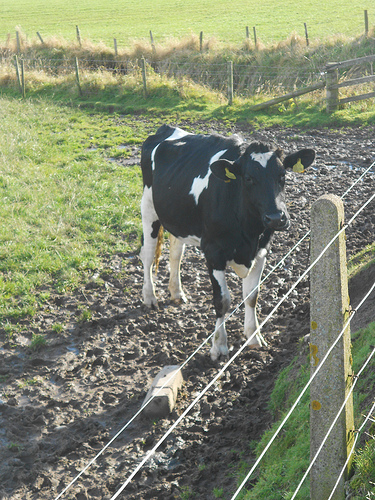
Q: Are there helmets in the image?
A: No, there are no helmets.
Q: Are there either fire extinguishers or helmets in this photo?
A: No, there are no helmets or fire extinguishers.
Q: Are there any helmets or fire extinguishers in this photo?
A: No, there are no helmets or fire extinguishers.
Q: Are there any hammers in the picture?
A: No, there are no hammers.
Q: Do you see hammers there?
A: No, there are no hammers.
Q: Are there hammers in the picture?
A: No, there are no hammers.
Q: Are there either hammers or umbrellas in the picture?
A: No, there are no hammers or umbrellas.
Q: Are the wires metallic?
A: Yes, the wires are metallic.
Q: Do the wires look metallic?
A: Yes, the wires are metallic.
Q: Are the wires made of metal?
A: Yes, the wires are made of metal.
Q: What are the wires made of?
A: The wires are made of metal.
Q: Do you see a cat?
A: No, there are no cats.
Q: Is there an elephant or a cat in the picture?
A: No, there are no cats or elephants.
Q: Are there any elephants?
A: No, there are no elephants.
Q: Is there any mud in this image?
A: Yes, there is mud.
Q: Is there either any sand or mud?
A: Yes, there is mud.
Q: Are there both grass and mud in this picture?
A: Yes, there are both mud and grass.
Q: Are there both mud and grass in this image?
A: Yes, there are both mud and grass.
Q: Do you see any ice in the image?
A: No, there is no ice.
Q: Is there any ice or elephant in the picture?
A: No, there are no ice or elephants.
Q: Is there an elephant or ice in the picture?
A: No, there are no ice or elephants.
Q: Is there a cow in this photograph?
A: Yes, there is a cow.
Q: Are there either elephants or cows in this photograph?
A: Yes, there is a cow.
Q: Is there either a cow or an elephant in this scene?
A: Yes, there is a cow.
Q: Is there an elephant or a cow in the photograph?
A: Yes, there is a cow.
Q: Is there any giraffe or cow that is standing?
A: Yes, the cow is standing.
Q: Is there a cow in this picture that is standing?
A: Yes, there is a cow that is standing.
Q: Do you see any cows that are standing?
A: Yes, there is a cow that is standing.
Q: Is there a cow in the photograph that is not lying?
A: Yes, there is a cow that is standing.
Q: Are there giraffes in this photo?
A: No, there are no giraffes.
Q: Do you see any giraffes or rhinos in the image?
A: No, there are no giraffes or rhinos.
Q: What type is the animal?
A: The animal is a cow.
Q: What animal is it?
A: The animal is a cow.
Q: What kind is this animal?
A: This is a cow.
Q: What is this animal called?
A: This is a cow.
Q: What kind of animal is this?
A: This is a cow.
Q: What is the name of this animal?
A: This is a cow.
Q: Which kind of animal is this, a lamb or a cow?
A: This is a cow.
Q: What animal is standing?
A: The animal is a cow.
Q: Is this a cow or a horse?
A: This is a cow.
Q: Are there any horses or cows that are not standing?
A: No, there is a cow but it is standing.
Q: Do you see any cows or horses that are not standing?
A: No, there is a cow but it is standing.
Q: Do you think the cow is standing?
A: Yes, the cow is standing.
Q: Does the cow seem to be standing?
A: Yes, the cow is standing.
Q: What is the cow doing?
A: The cow is standing.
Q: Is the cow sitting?
A: No, the cow is standing.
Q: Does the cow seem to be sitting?
A: No, the cow is standing.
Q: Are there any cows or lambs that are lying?
A: No, there is a cow but it is standing.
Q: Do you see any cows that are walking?
A: No, there is a cow but it is standing.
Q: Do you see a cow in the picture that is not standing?
A: No, there is a cow but it is standing.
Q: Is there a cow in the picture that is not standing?
A: No, there is a cow but it is standing.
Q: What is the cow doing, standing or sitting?
A: The cow is standing.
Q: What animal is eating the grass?
A: The cow is eating the grass.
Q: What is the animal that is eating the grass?
A: The animal is a cow.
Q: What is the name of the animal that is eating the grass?
A: The animal is a cow.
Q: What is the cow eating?
A: The cow is eating grass.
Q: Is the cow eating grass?
A: Yes, the cow is eating grass.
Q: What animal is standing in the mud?
A: The cow is standing in the mud.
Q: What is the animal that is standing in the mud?
A: The animal is a cow.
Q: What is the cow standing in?
A: The cow is standing in the mud.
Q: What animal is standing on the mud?
A: The cow is standing on the mud.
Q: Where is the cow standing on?
A: The cow is standing on the mud.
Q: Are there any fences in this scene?
A: Yes, there is a fence.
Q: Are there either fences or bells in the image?
A: Yes, there is a fence.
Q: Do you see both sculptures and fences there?
A: No, there is a fence but no sculptures.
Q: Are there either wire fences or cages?
A: Yes, there is a wire fence.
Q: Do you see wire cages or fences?
A: Yes, there is a wire fence.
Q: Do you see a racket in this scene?
A: No, there are no rackets.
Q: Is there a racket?
A: No, there are no rackets.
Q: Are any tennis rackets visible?
A: No, there are no tennis rackets.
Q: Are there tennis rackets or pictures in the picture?
A: No, there are no tennis rackets or pictures.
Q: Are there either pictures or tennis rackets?
A: No, there are no tennis rackets or pictures.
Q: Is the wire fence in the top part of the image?
A: Yes, the fence is in the top of the image.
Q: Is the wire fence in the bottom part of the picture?
A: No, the fence is in the top of the image.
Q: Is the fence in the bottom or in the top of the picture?
A: The fence is in the top of the image.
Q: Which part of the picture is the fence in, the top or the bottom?
A: The fence is in the top of the image.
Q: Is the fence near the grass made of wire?
A: Yes, the fence is made of wire.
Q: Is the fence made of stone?
A: No, the fence is made of wire.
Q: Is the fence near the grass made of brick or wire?
A: The fence is made of wire.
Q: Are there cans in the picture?
A: No, there are no cans.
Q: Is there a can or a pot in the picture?
A: No, there are no cans or pots.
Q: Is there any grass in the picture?
A: Yes, there is grass.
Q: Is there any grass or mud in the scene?
A: Yes, there is grass.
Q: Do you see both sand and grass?
A: No, there is grass but no sand.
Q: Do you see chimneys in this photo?
A: No, there are no chimneys.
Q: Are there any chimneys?
A: No, there are no chimneys.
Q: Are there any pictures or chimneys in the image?
A: No, there are no chimneys or pictures.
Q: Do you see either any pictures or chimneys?
A: No, there are no chimneys or pictures.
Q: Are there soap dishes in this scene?
A: No, there are no soap dishes.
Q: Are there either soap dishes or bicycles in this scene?
A: No, there are no soap dishes or bicycles.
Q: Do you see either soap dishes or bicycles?
A: No, there are no soap dishes or bicycles.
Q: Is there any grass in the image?
A: Yes, there is grass.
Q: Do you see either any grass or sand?
A: Yes, there is grass.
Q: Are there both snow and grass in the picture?
A: No, there is grass but no snow.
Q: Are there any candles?
A: No, there are no candles.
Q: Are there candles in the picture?
A: No, there are no candles.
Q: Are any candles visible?
A: No, there are no candles.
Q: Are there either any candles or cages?
A: No, there are no candles or cages.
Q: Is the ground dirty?
A: Yes, the ground is dirty.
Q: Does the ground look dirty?
A: Yes, the ground is dirty.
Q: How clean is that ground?
A: The ground is dirty.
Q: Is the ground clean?
A: No, the ground is dirty.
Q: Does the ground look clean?
A: No, the ground is dirty.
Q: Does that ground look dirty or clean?
A: The ground is dirty.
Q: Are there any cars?
A: No, there are no cars.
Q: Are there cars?
A: No, there are no cars.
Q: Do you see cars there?
A: No, there are no cars.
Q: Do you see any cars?
A: No, there are no cars.